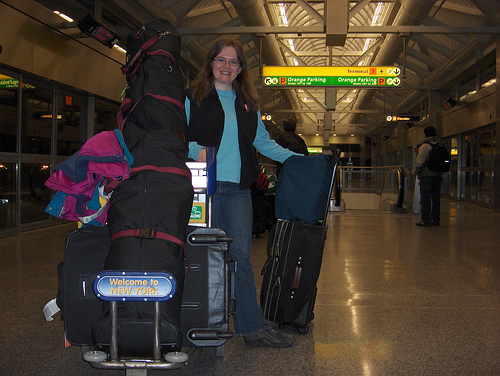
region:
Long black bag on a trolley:
[87, 11, 190, 371]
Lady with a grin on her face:
[176, 34, 311, 358]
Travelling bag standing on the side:
[255, 131, 349, 336]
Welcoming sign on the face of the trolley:
[66, 269, 191, 374]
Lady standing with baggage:
[42, 15, 346, 370]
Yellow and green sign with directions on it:
[258, 61, 407, 92]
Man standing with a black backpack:
[406, 120, 456, 233]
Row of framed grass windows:
[2, 59, 120, 244]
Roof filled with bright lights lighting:
[251, 1, 432, 149]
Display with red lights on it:
[77, 13, 120, 55]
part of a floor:
[391, 328, 410, 350]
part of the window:
[41, 195, 62, 213]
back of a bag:
[208, 305, 229, 332]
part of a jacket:
[248, 160, 254, 165]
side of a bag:
[282, 280, 298, 293]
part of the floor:
[399, 261, 416, 282]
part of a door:
[476, 150, 493, 162]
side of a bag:
[131, 223, 148, 248]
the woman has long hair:
[193, 39, 262, 107]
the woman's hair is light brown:
[196, 40, 257, 106]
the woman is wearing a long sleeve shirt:
[181, 84, 309, 183]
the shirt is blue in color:
[181, 88, 310, 187]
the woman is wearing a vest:
[187, 83, 260, 191]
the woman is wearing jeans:
[204, 180, 271, 334]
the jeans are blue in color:
[208, 181, 265, 329]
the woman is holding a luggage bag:
[263, 153, 336, 334]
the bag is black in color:
[261, 157, 339, 339]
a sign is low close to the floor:
[94, 272, 172, 300]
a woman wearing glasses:
[198, 35, 254, 88]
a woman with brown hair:
[198, 40, 255, 105]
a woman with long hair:
[186, 29, 264, 106]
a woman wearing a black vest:
[194, 73, 270, 173]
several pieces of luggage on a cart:
[51, 58, 251, 373]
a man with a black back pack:
[418, 129, 452, 191]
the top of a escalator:
[331, 166, 407, 219]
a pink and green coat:
[46, 124, 138, 234]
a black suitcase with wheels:
[257, 209, 343, 340]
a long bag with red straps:
[113, 19, 179, 291]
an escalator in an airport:
[332, 165, 404, 215]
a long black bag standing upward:
[108, 18, 188, 356]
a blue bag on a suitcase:
[273, 148, 332, 225]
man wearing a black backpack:
[416, 137, 451, 173]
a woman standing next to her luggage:
[182, 38, 307, 348]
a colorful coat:
[44, 125, 135, 221]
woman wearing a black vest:
[186, 83, 258, 185]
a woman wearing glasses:
[212, 57, 238, 68]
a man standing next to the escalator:
[411, 120, 446, 226]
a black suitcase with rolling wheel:
[260, 215, 327, 334]